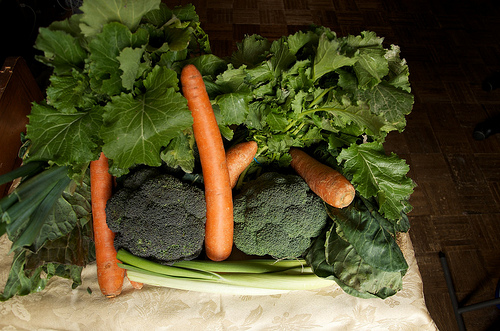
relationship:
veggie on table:
[229, 172, 328, 262] [2, 205, 442, 329]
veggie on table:
[229, 172, 328, 262] [5, 131, 432, 327]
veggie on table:
[93, 165, 210, 265] [5, 6, 492, 329]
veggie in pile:
[104, 165, 211, 265] [32, 7, 411, 276]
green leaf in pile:
[116, 42, 149, 87] [0, 0, 419, 300]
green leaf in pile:
[333, 139, 415, 225] [0, 0, 419, 300]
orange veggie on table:
[84, 154, 134, 303] [404, 8, 498, 256]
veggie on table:
[67, 8, 172, 135] [5, 6, 492, 329]